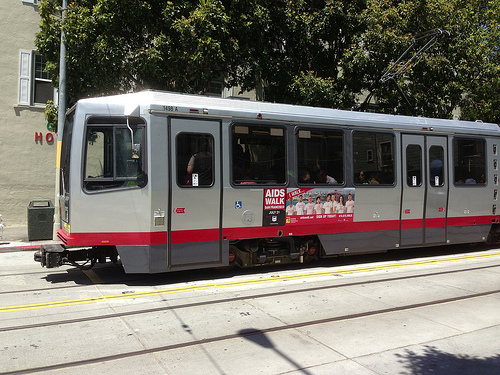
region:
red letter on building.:
[31, 130, 47, 148]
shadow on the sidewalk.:
[407, 352, 457, 367]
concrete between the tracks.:
[118, 314, 145, 349]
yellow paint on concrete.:
[223, 279, 272, 286]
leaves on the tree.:
[364, 18, 381, 39]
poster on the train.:
[258, 190, 353, 225]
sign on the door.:
[187, 170, 202, 187]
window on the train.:
[100, 137, 125, 177]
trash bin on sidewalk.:
[25, 200, 52, 239]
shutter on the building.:
[17, 50, 29, 109]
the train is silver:
[52, 73, 486, 265]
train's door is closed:
[153, 105, 238, 262]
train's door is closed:
[385, 110, 473, 262]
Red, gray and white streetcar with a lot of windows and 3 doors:
[44, 90, 496, 274]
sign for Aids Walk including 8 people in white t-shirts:
[263, 188, 353, 227]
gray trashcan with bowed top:
[26, 200, 58, 240]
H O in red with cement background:
[33, 131, 53, 146]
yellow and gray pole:
[55, 108, 62, 247]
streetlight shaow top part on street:
[228, 326, 318, 373]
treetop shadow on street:
[392, 346, 491, 373]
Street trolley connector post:
[29, 243, 116, 266]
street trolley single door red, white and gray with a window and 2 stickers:
[166, 113, 224, 265]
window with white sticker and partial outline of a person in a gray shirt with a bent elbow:
[173, 131, 215, 188]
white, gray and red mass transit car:
[32, 90, 493, 278]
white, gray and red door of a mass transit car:
[161, 112, 227, 274]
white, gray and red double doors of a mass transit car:
[397, 127, 452, 251]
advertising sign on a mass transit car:
[260, 184, 354, 226]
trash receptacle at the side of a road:
[25, 197, 54, 240]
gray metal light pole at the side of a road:
[55, 0, 67, 259]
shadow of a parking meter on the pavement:
[236, 325, 315, 373]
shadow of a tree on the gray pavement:
[393, 343, 495, 373]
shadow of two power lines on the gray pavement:
[0, 263, 497, 370]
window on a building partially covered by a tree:
[15, 45, 70, 117]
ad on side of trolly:
[264, 184, 354, 227]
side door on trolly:
[165, 116, 225, 268]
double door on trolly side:
[395, 127, 454, 249]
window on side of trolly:
[228, 122, 395, 188]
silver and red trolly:
[53, 82, 498, 264]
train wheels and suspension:
[235, 241, 321, 270]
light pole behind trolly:
[49, 7, 60, 247]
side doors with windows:
[398, 136, 447, 253]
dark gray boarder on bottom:
[112, 227, 493, 274]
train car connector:
[31, 237, 112, 281]